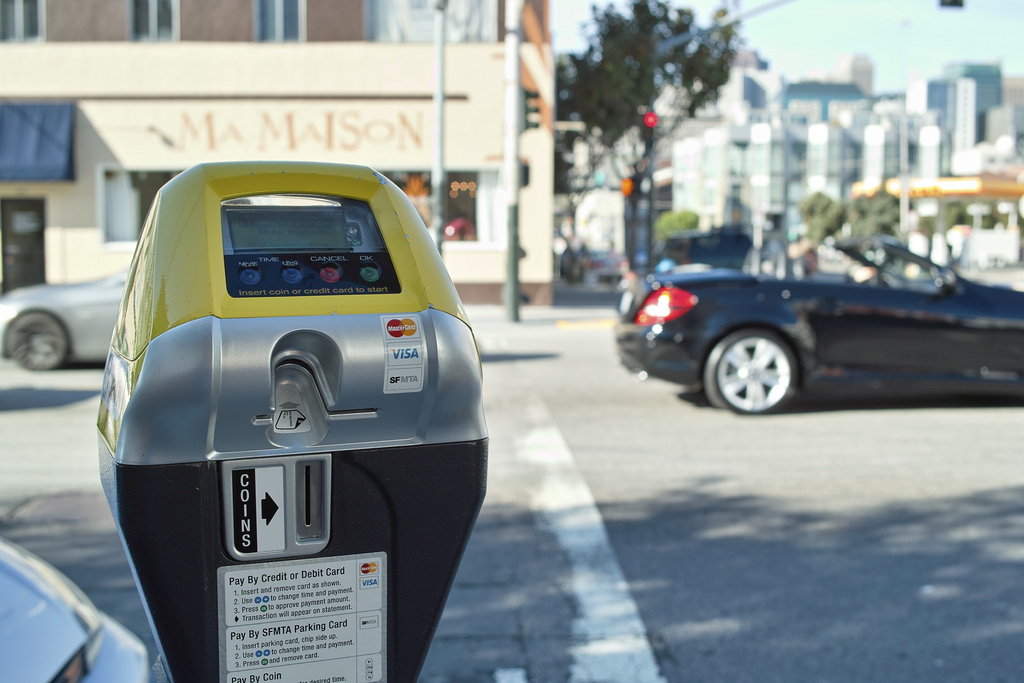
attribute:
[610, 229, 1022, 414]
vehicle — black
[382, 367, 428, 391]
logo —  represent payments accepted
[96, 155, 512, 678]
parking meter — black, yellow, parking , directions 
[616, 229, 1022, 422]
sportscar — black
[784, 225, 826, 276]
white man — convertible, old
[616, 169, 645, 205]
pedestrian light — pedestrian , traffic  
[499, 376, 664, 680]
white stripe — worn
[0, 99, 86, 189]
awning — blue